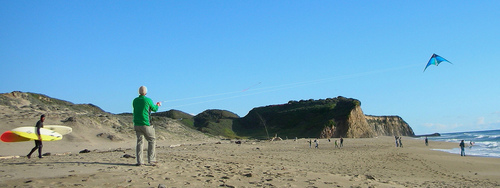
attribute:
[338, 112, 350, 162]
ground — flying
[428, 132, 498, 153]
waves — blue, white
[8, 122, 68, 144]
surfboard — yellow, white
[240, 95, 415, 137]
cliffs — standing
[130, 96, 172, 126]
shirt — green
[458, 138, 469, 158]
person — standing, distant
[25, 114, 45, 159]
man — black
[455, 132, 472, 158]
person — standing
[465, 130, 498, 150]
waves — small, rolling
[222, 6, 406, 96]
sky — pleasent, blue, cloudless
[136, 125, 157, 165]
pants — khaki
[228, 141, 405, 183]
beach — wide, sandy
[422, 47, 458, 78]
kite — large, blue, flying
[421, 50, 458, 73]
kite — blue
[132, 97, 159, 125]
shirt — green, long sleeved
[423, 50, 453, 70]
kite — blue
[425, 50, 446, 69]
kite — blue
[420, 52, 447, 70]
kite — blue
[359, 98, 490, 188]
water — foamy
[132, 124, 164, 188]
pants — khaki